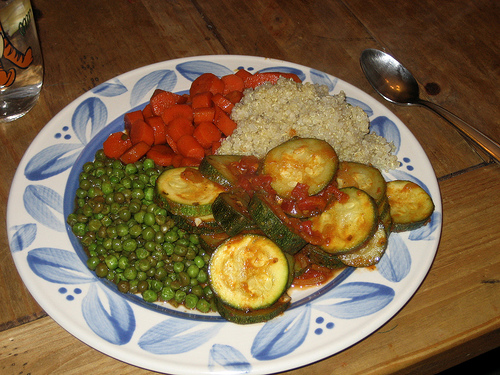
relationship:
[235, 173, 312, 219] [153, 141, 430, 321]
sauce on zucchini